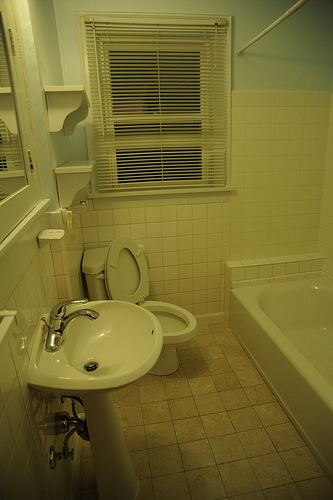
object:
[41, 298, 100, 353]
faucet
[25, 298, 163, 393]
sink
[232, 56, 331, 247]
wall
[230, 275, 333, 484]
bathtub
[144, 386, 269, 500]
floor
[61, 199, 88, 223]
towel holder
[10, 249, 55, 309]
wall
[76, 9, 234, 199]
window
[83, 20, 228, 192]
blinds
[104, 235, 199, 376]
toilet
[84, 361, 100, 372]
drain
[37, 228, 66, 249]
soap dish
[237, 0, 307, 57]
shower curtain rod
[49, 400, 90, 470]
plumbing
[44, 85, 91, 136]
shelf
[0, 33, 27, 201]
mirror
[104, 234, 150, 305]
toilet seat